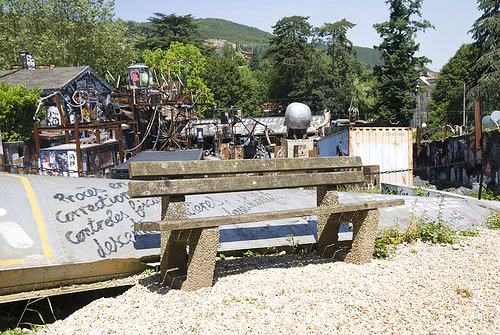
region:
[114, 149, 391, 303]
Grey and brown cement bench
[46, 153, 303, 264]
Blue writing on ground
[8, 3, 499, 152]
Group of trees in the distance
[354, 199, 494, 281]
Group of weeds by the bench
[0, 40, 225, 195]
Small blue building in the background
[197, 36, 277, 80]
Group of buildings in the distance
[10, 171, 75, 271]
Yellow line on sidewalk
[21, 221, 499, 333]
Brown and white pebbles on the ground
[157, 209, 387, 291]
Brown cement legs on bench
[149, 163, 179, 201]
Two black bolts on bench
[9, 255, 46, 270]
gray paint on wall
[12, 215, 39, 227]
gray paint on wall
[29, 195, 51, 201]
gray paint on wall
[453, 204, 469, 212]
gray paint on wall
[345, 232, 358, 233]
gray paint on wall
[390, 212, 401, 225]
gray paint on wall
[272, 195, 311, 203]
gray paint on wall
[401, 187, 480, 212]
gray paint on wall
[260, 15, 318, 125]
THAT IS A TREE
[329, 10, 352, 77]
THAT IS A TREE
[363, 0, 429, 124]
THAT IS A TREE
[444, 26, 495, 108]
THAT IS A TREE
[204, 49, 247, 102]
THAT IS A TREE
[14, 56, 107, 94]
THAT IS A HOUSE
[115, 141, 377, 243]
THAT IS A BENCH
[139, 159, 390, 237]
THAT IS A WOODEN BENCH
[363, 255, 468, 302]
THAT IS THE GROUND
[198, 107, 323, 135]
THAT IS A ROOF OF A HOUSE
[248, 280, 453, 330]
The ground has gravel on it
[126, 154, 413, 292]
The bench on the ground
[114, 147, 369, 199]
The back of the bench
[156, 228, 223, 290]
The leg of the bench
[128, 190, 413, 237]
The seat of the bench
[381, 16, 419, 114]
The tree is the color brown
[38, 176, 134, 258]
The writing on the ground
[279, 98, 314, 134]
The ball is the color silver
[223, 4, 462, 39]
The sky is clear and blue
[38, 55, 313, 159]
Various different buildings on the ground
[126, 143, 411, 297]
an empty bench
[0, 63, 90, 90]
a roof of the house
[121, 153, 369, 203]
a backrest of the bench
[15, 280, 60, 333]
a tall grass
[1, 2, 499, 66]
tree lines in the background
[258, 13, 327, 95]
a green tree in the background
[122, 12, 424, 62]
a mountain line in the background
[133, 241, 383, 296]
a shadow of the bench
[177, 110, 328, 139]
a roof the house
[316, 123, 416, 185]
a container in the background